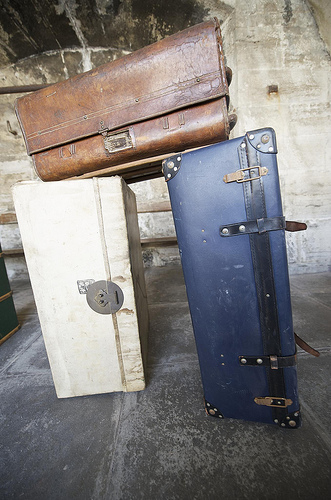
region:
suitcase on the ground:
[161, 130, 298, 420]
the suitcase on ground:
[26, 177, 149, 409]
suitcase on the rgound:
[7, 74, 237, 166]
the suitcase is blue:
[204, 287, 276, 366]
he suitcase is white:
[54, 329, 123, 370]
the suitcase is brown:
[119, 67, 179, 97]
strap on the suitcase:
[221, 343, 288, 369]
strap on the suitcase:
[203, 211, 282, 242]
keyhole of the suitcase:
[64, 284, 117, 316]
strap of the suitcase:
[79, 120, 134, 154]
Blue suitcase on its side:
[162, 127, 301, 426]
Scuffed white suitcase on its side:
[12, 178, 149, 396]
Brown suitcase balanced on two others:
[3, 21, 235, 178]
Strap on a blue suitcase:
[255, 394, 292, 408]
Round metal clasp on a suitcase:
[86, 280, 126, 315]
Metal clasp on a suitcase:
[225, 167, 271, 181]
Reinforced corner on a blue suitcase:
[252, 126, 279, 154]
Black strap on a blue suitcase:
[238, 354, 294, 367]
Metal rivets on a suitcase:
[222, 223, 245, 233]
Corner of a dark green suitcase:
[0, 245, 22, 339]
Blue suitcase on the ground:
[161, 127, 299, 424]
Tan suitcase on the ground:
[9, 174, 145, 397]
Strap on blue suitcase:
[220, 221, 283, 236]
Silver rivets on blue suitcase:
[222, 224, 246, 234]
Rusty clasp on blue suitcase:
[257, 392, 290, 409]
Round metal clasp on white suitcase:
[84, 280, 123, 315]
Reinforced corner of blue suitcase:
[249, 127, 277, 154]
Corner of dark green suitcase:
[1, 248, 20, 346]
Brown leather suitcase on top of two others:
[15, 20, 230, 179]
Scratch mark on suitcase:
[69, 95, 93, 114]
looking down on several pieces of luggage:
[0, 7, 324, 434]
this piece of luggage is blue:
[160, 125, 318, 428]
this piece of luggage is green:
[0, 228, 23, 352]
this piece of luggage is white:
[5, 169, 154, 401]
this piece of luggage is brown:
[10, 9, 241, 184]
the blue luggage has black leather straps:
[212, 201, 324, 372]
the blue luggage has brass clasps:
[218, 159, 270, 182]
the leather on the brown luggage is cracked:
[10, 11, 238, 187]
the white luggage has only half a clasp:
[79, 270, 130, 322]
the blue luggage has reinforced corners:
[242, 123, 281, 158]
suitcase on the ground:
[8, 165, 165, 387]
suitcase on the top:
[17, 42, 269, 177]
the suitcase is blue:
[195, 286, 233, 346]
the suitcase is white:
[57, 337, 108, 375]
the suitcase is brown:
[79, 68, 170, 108]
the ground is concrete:
[67, 404, 241, 483]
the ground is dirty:
[151, 431, 275, 481]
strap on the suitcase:
[234, 343, 304, 361]